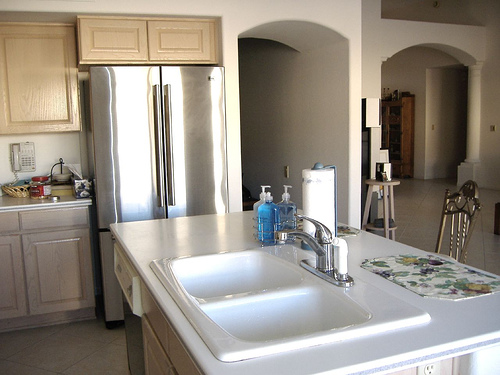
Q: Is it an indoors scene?
A: Yes, it is indoors.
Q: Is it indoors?
A: Yes, it is indoors.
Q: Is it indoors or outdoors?
A: It is indoors.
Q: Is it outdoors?
A: No, it is indoors.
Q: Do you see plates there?
A: No, there are no plates.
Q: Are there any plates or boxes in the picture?
A: No, there are no plates or boxes.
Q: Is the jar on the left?
A: Yes, the jar is on the left of the image.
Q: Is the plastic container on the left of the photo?
A: Yes, the jar is on the left of the image.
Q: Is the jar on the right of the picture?
A: No, the jar is on the left of the image.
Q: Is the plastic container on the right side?
A: No, the jar is on the left of the image.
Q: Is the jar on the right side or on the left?
A: The jar is on the left of the image.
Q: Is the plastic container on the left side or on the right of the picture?
A: The jar is on the left of the image.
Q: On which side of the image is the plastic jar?
A: The jar is on the left of the image.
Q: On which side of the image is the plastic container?
A: The jar is on the left of the image.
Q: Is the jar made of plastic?
A: Yes, the jar is made of plastic.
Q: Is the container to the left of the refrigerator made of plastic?
A: Yes, the jar is made of plastic.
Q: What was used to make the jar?
A: The jar is made of plastic.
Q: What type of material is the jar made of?
A: The jar is made of plastic.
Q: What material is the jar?
A: The jar is made of plastic.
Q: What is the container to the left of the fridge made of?
A: The jar is made of plastic.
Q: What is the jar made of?
A: The jar is made of plastic.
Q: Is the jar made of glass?
A: No, the jar is made of plastic.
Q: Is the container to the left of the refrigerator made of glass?
A: No, the jar is made of plastic.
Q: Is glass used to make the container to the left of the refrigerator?
A: No, the jar is made of plastic.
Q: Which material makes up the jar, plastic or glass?
A: The jar is made of plastic.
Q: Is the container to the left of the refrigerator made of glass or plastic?
A: The jar is made of plastic.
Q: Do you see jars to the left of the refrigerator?
A: Yes, there is a jar to the left of the refrigerator.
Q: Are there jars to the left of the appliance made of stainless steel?
A: Yes, there is a jar to the left of the refrigerator.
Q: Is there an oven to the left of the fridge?
A: No, there is a jar to the left of the fridge.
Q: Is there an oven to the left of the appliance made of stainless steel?
A: No, there is a jar to the left of the fridge.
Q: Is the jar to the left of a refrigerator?
A: Yes, the jar is to the left of a refrigerator.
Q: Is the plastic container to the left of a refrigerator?
A: Yes, the jar is to the left of a refrigerator.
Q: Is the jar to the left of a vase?
A: No, the jar is to the left of a refrigerator.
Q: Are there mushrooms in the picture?
A: No, there are no mushrooms.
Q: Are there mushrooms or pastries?
A: No, there are no mushrooms or pastries.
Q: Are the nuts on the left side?
A: Yes, the nuts are on the left of the image.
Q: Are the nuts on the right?
A: No, the nuts are on the left of the image.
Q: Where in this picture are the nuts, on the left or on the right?
A: The nuts are on the left of the image.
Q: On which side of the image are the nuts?
A: The nuts are on the left of the image.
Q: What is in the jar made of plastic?
A: The nuts are in the jar.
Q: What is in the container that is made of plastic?
A: The nuts are in the jar.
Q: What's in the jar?
A: The nuts are in the jar.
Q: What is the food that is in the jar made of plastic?
A: The food is nuts.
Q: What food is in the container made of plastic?
A: The food is nuts.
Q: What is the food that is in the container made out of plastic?
A: The food is nuts.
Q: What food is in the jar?
A: The food is nuts.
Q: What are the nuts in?
A: The nuts are in the jar.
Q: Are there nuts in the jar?
A: Yes, there are nuts in the jar.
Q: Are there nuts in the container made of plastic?
A: Yes, there are nuts in the jar.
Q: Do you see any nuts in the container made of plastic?
A: Yes, there are nuts in the jar.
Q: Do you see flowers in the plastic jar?
A: No, there are nuts in the jar.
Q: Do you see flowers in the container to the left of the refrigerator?
A: No, there are nuts in the jar.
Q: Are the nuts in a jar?
A: Yes, the nuts are in a jar.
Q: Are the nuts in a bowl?
A: No, the nuts are in a jar.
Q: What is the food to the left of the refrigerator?
A: The food is nuts.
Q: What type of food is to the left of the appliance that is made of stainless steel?
A: The food is nuts.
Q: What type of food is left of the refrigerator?
A: The food is nuts.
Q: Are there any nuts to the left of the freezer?
A: Yes, there are nuts to the left of the freezer.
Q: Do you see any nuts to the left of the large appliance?
A: Yes, there are nuts to the left of the freezer.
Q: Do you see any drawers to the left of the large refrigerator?
A: No, there are nuts to the left of the refrigerator.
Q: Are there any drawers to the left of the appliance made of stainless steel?
A: No, there are nuts to the left of the refrigerator.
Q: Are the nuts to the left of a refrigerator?
A: Yes, the nuts are to the left of a refrigerator.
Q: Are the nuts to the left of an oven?
A: No, the nuts are to the left of a refrigerator.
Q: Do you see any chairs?
A: Yes, there is a chair.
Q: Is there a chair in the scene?
A: Yes, there is a chair.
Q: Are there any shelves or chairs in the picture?
A: Yes, there is a chair.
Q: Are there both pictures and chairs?
A: No, there is a chair but no pictures.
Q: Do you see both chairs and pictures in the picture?
A: No, there is a chair but no pictures.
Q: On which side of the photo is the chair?
A: The chair is on the right of the image.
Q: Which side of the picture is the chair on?
A: The chair is on the right of the image.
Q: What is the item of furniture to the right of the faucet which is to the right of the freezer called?
A: The piece of furniture is a chair.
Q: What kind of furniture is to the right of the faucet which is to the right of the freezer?
A: The piece of furniture is a chair.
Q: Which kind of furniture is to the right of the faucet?
A: The piece of furniture is a chair.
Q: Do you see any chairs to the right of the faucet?
A: Yes, there is a chair to the right of the faucet.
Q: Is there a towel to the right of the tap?
A: No, there is a chair to the right of the tap.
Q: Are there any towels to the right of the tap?
A: No, there is a chair to the right of the tap.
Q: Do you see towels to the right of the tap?
A: No, there is a chair to the right of the tap.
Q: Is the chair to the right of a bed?
A: No, the chair is to the right of the faucet.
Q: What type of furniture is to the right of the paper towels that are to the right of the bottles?
A: The piece of furniture is a chair.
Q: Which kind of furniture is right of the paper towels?
A: The piece of furniture is a chair.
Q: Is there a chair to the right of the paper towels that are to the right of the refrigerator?
A: Yes, there is a chair to the right of the paper towels.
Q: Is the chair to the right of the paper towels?
A: Yes, the chair is to the right of the paper towels.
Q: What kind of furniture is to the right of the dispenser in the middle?
A: The piece of furniture is a chair.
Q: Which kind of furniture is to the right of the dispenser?
A: The piece of furniture is a chair.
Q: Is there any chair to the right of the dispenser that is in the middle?
A: Yes, there is a chair to the right of the dispenser.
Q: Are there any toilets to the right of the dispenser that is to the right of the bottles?
A: No, there is a chair to the right of the dispenser.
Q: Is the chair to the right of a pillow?
A: No, the chair is to the right of a dispenser.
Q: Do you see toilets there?
A: No, there are no toilets.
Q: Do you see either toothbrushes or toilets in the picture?
A: No, there are no toilets or toothbrushes.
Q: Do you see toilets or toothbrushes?
A: No, there are no toilets or toothbrushes.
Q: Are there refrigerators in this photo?
A: Yes, there is a refrigerator.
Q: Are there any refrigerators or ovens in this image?
A: Yes, there is a refrigerator.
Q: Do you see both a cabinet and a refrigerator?
A: Yes, there are both a refrigerator and a cabinet.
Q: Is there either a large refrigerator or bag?
A: Yes, there is a large refrigerator.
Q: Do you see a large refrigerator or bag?
A: Yes, there is a large refrigerator.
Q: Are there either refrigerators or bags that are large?
A: Yes, the refrigerator is large.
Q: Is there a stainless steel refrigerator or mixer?
A: Yes, there is a stainless steel refrigerator.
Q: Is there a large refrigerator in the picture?
A: Yes, there is a large refrigerator.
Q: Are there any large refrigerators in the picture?
A: Yes, there is a large refrigerator.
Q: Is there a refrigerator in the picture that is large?
A: Yes, there is a refrigerator that is large.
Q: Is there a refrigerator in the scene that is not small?
A: Yes, there is a large refrigerator.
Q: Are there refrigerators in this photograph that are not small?
A: Yes, there is a large refrigerator.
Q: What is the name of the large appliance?
A: The appliance is a refrigerator.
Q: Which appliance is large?
A: The appliance is a refrigerator.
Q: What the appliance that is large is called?
A: The appliance is a refrigerator.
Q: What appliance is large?
A: The appliance is a refrigerator.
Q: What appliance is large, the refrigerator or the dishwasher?
A: The refrigerator is large.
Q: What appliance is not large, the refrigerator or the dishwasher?
A: The dishwasher is not large.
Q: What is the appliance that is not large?
A: The appliance is a dishwasher.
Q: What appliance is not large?
A: The appliance is a dishwasher.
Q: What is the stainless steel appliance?
A: The appliance is a refrigerator.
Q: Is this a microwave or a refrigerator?
A: This is a refrigerator.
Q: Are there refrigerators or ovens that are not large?
A: No, there is a refrigerator but it is large.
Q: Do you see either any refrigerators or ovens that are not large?
A: No, there is a refrigerator but it is large.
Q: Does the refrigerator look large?
A: Yes, the refrigerator is large.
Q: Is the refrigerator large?
A: Yes, the refrigerator is large.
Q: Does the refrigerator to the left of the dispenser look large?
A: Yes, the fridge is large.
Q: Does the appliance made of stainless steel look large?
A: Yes, the fridge is large.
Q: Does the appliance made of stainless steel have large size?
A: Yes, the fridge is large.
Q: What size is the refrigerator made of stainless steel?
A: The refrigerator is large.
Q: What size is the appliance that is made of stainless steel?
A: The refrigerator is large.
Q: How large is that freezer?
A: The freezer is large.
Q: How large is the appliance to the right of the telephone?
A: The freezer is large.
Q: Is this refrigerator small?
A: No, the refrigerator is large.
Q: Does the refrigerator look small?
A: No, the refrigerator is large.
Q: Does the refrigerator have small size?
A: No, the refrigerator is large.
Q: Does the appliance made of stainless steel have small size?
A: No, the refrigerator is large.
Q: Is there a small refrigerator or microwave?
A: No, there is a refrigerator but it is large.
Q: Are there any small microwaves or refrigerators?
A: No, there is a refrigerator but it is large.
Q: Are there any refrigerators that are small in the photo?
A: No, there is a refrigerator but it is large.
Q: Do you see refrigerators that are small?
A: No, there is a refrigerator but it is large.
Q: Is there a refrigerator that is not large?
A: No, there is a refrigerator but it is large.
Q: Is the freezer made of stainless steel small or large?
A: The freezer is large.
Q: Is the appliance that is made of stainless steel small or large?
A: The freezer is large.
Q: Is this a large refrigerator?
A: Yes, this is a large refrigerator.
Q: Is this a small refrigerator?
A: No, this is a large refrigerator.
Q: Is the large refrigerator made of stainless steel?
A: Yes, the refrigerator is made of stainless steel.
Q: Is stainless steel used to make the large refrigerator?
A: Yes, the refrigerator is made of stainless steel.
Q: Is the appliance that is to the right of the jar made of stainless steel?
A: Yes, the refrigerator is made of stainless steel.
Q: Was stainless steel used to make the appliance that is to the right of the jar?
A: Yes, the refrigerator is made of stainless steel.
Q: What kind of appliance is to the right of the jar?
A: The appliance is a refrigerator.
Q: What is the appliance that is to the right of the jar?
A: The appliance is a refrigerator.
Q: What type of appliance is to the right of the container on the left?
A: The appliance is a refrigerator.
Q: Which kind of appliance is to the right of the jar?
A: The appliance is a refrigerator.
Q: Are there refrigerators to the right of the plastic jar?
A: Yes, there is a refrigerator to the right of the jar.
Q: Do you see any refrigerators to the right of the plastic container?
A: Yes, there is a refrigerator to the right of the jar.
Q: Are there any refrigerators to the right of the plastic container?
A: Yes, there is a refrigerator to the right of the jar.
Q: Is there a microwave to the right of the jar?
A: No, there is a refrigerator to the right of the jar.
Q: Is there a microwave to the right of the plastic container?
A: No, there is a refrigerator to the right of the jar.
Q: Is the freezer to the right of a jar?
A: Yes, the freezer is to the right of a jar.